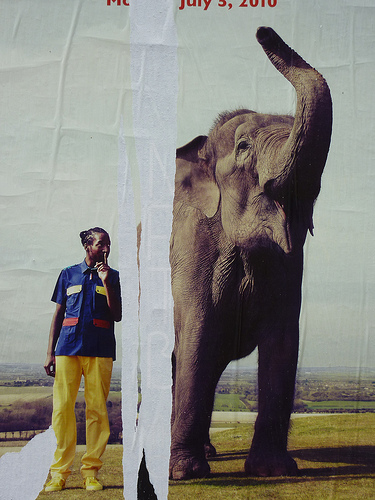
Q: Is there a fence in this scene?
A: No, there are no fences.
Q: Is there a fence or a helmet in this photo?
A: No, there are no fences or helmets.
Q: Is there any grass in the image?
A: Yes, there is grass.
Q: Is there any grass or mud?
A: Yes, there is grass.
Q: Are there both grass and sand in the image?
A: No, there is grass but no sand.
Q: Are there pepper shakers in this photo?
A: No, there are no pepper shakers.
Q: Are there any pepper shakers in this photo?
A: No, there are no pepper shakers.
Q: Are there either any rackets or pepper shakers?
A: No, there are no pepper shakers or rackets.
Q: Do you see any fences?
A: No, there are no fences.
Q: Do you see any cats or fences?
A: No, there are no fences or cats.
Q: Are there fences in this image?
A: No, there are no fences.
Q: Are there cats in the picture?
A: No, there are no cats.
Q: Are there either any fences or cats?
A: No, there are no cats or fences.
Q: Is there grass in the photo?
A: Yes, there is grass.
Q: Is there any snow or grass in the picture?
A: Yes, there is grass.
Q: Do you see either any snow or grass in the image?
A: Yes, there is grass.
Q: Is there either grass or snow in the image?
A: Yes, there is grass.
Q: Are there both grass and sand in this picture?
A: No, there is grass but no sand.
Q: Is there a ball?
A: No, there are no balls.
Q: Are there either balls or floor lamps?
A: No, there are no balls or floor lamps.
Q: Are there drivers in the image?
A: No, there are no drivers.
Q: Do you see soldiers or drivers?
A: No, there are no drivers or soldiers.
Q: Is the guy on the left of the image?
A: Yes, the guy is on the left of the image.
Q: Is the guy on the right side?
A: No, the guy is on the left of the image.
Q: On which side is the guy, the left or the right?
A: The guy is on the left of the image.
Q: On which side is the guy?
A: The guy is on the left of the image.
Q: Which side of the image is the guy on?
A: The guy is on the left of the image.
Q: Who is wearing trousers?
A: The guy is wearing trousers.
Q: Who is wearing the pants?
A: The guy is wearing trousers.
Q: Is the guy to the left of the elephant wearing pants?
A: Yes, the guy is wearing pants.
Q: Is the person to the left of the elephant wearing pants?
A: Yes, the guy is wearing pants.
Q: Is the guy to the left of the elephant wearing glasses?
A: No, the guy is wearing pants.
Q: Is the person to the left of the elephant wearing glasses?
A: No, the guy is wearing pants.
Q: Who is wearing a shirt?
A: The guy is wearing a shirt.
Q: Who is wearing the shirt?
A: The guy is wearing a shirt.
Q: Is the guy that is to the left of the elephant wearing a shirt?
A: Yes, the guy is wearing a shirt.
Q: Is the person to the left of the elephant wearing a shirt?
A: Yes, the guy is wearing a shirt.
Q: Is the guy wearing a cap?
A: No, the guy is wearing a shirt.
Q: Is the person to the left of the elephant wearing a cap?
A: No, the guy is wearing a shirt.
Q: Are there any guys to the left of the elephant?
A: Yes, there is a guy to the left of the elephant.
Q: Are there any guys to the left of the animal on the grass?
A: Yes, there is a guy to the left of the elephant.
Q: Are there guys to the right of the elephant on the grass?
A: No, the guy is to the left of the elephant.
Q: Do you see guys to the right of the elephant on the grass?
A: No, the guy is to the left of the elephant.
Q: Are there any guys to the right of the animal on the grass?
A: No, the guy is to the left of the elephant.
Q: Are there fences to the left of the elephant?
A: No, there is a guy to the left of the elephant.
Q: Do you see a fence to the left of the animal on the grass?
A: No, there is a guy to the left of the elephant.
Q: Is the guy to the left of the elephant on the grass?
A: Yes, the guy is to the left of the elephant.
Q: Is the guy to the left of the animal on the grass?
A: Yes, the guy is to the left of the elephant.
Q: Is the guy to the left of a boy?
A: No, the guy is to the left of the elephant.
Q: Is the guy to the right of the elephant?
A: No, the guy is to the left of the elephant.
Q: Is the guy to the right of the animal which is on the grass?
A: No, the guy is to the left of the elephant.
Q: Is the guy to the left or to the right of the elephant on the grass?
A: The guy is to the left of the elephant.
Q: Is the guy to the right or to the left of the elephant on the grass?
A: The guy is to the left of the elephant.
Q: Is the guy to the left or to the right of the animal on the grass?
A: The guy is to the left of the elephant.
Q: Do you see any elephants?
A: Yes, there is an elephant.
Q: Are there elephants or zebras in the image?
A: Yes, there is an elephant.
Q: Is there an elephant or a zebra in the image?
A: Yes, there is an elephant.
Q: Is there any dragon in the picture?
A: No, there are no dragons.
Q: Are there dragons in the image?
A: No, there are no dragons.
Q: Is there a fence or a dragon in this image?
A: No, there are no dragons or fences.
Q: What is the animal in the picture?
A: The animal is an elephant.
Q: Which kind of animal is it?
A: The animal is an elephant.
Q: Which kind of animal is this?
A: That is an elephant.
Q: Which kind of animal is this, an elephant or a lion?
A: That is an elephant.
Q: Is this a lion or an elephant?
A: This is an elephant.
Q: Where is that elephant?
A: The elephant is on the grass.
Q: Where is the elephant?
A: The elephant is on the grass.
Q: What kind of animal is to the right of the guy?
A: The animal is an elephant.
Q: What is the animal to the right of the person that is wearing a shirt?
A: The animal is an elephant.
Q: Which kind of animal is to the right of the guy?
A: The animal is an elephant.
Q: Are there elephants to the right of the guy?
A: Yes, there is an elephant to the right of the guy.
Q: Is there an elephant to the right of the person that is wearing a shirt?
A: Yes, there is an elephant to the right of the guy.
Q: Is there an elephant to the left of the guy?
A: No, the elephant is to the right of the guy.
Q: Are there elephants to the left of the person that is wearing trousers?
A: No, the elephant is to the right of the guy.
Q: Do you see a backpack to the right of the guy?
A: No, there is an elephant to the right of the guy.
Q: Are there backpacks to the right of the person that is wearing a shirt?
A: No, there is an elephant to the right of the guy.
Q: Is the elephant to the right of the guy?
A: Yes, the elephant is to the right of the guy.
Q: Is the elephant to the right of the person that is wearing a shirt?
A: Yes, the elephant is to the right of the guy.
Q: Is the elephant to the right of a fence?
A: No, the elephant is to the right of the guy.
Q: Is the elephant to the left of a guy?
A: No, the elephant is to the right of a guy.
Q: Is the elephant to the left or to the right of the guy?
A: The elephant is to the right of the guy.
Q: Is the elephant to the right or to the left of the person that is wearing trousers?
A: The elephant is to the right of the guy.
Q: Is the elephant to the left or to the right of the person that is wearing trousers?
A: The elephant is to the right of the guy.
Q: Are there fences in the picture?
A: No, there are no fences.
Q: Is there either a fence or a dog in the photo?
A: No, there are no fences or dogs.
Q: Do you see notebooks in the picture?
A: No, there are no notebooks.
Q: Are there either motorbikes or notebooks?
A: No, there are no notebooks or motorbikes.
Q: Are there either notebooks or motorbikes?
A: No, there are no notebooks or motorbikes.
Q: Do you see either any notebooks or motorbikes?
A: No, there are no notebooks or motorbikes.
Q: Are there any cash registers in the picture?
A: No, there are no cash registers.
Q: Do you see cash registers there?
A: No, there are no cash registers.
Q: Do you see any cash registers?
A: No, there are no cash registers.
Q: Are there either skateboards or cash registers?
A: No, there are no cash registers or skateboards.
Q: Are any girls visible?
A: No, there are no girls.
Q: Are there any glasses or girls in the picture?
A: No, there are no girls or glasses.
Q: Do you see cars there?
A: No, there are no cars.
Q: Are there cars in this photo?
A: No, there are no cars.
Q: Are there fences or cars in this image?
A: No, there are no cars or fences.